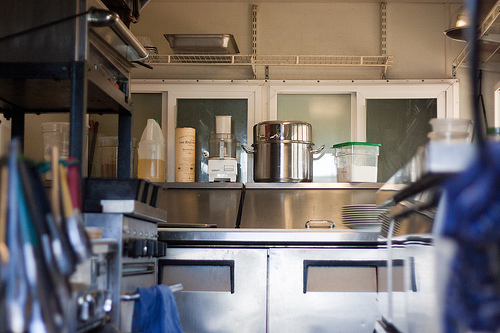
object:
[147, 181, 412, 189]
shelf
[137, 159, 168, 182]
liquid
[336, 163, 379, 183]
powder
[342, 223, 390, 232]
plates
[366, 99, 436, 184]
glass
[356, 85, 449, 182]
cabinet door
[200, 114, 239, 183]
mixer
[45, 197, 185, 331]
appliance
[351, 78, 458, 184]
cabinets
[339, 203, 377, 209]
dishes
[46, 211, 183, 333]
stove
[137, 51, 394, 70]
rack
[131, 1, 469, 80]
wall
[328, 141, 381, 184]
container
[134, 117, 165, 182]
bottle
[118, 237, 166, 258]
knobs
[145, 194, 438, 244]
lid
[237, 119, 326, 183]
pot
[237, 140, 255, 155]
handles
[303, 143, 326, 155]
handle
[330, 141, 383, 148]
lid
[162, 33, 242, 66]
pan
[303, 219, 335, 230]
handle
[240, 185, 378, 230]
drawer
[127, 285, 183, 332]
dishcloth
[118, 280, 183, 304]
handle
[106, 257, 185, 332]
oven door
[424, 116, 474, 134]
container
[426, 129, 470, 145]
container